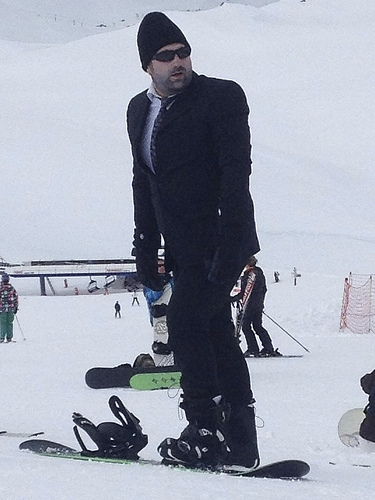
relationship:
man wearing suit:
[104, 9, 282, 390] [123, 85, 254, 269]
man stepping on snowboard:
[104, 9, 282, 390] [86, 440, 245, 488]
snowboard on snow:
[18, 394, 310, 481] [0, 0, 374, 498]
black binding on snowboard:
[72, 396, 150, 458] [18, 436, 311, 480]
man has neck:
[126, 10, 261, 475] [147, 70, 209, 106]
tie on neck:
[142, 92, 188, 175] [147, 70, 209, 106]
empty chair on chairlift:
[86, 278, 102, 294] [0, 255, 175, 297]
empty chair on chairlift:
[102, 271, 116, 288] [0, 255, 175, 297]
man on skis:
[238, 247, 295, 370] [222, 341, 313, 366]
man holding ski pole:
[238, 247, 295, 370] [250, 298, 317, 355]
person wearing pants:
[2, 272, 23, 349] [0, 305, 20, 338]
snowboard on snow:
[18, 436, 311, 480] [0, 0, 374, 498]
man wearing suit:
[126, 10, 261, 475] [126, 71, 261, 392]